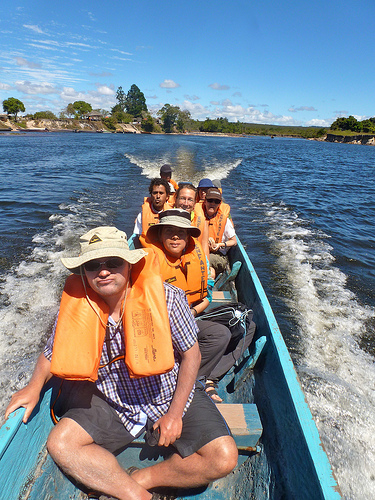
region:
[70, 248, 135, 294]
A man with sunglasses with a neutral expression.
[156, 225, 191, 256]
A woman with a neutral expression.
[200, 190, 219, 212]
A man with a hat and sunglasses.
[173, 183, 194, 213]
A happy older woman with a smile.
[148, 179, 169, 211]
A young man with a puzzled expression.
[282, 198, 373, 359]
A ripple of water across the sea.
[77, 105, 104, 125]
A tent area off of the shore.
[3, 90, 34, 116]
A tree.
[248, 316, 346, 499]
The side of a cyan blue boat.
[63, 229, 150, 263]
A khaki hat.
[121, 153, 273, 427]
The people have on life vests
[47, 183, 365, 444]
These people are on a boat ride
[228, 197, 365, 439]
There are waves in the water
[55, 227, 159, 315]
This man has a hat on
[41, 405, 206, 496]
The man has shorts on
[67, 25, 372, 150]
The weather is sunny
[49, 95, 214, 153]
There are trees in the back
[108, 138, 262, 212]
There is a trail behind the boat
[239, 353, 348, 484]
The boat is blue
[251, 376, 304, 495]
The boat is made of wood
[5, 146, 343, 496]
A group of people in a boat.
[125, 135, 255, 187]
The wake of the boat.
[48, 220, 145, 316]
The man is wearing a hat.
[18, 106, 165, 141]
A dock and buildings in the distance.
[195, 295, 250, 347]
A black bag.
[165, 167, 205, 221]
The person is smiling.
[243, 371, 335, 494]
The boat is turquoise.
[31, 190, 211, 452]
The man is wearing a plaid shirt.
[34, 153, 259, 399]
The people are wearing life jackets.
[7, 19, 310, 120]
Clouds in the sky.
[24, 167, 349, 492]
people in a blue wooden canoe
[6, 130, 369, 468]
a river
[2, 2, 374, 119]
blue clear sky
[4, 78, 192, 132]
trees on riverbank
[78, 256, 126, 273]
dark sunglasses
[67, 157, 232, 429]
people wearing orange life-jacket on a boat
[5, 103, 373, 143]
riverbank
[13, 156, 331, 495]
blue canoe on a river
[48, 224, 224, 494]
man in front wearing a life jacket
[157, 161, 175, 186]
person at the tail end of boat wearing a cap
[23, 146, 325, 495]
There are 7 people in the boat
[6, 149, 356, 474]
The boat is creating waves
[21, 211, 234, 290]
These two are wearing brown hats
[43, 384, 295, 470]
The man has on black shorts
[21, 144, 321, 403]
Everyone is wearing a life jacket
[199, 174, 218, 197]
This person has on a blue hat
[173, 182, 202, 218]
The lady is smiling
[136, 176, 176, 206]
The man's hair is black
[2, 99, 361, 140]
Trees are showing in the background